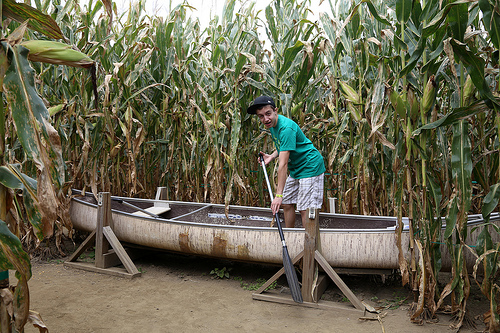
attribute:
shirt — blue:
[260, 112, 326, 178]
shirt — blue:
[266, 122, 323, 174]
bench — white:
[134, 202, 169, 218]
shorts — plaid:
[277, 175, 327, 211]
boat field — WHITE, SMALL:
[65, 202, 499, 284]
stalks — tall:
[1, 0, 498, 331]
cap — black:
[246, 93, 281, 113]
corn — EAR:
[13, 35, 95, 70]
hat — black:
[248, 94, 272, 114]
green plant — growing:
[204, 264, 229, 276]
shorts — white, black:
[233, 155, 356, 214]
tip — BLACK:
[271, 216, 299, 300]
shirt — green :
[270, 106, 329, 178]